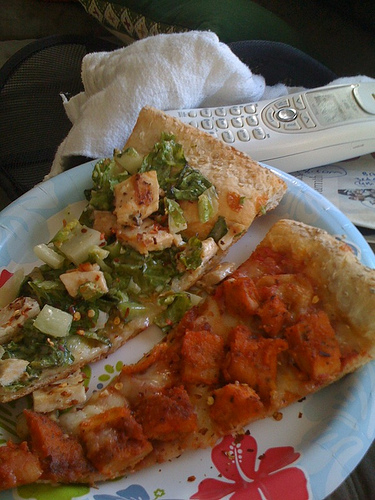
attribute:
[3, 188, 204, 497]
plate — floral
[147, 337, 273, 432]
meat — orange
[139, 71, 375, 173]
phone — white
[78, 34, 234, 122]
cloth — white, wite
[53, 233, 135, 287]
vegetable — green